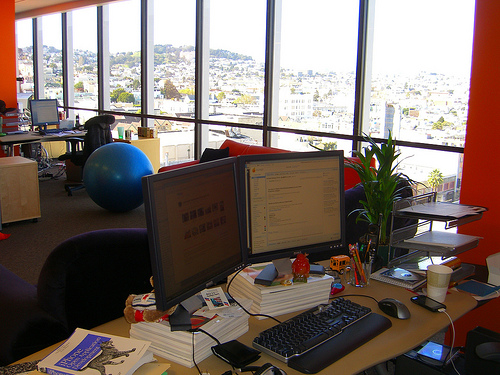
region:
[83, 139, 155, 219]
the ball is blue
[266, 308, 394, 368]
the keyboard is black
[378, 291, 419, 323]
the mouse is grey and black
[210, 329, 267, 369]
wallet is on the table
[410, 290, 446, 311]
iphone is on the table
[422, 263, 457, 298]
the cup is plastic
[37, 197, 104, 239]
the floor is carpeted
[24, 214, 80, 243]
the carpet is brown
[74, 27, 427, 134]
city is in the background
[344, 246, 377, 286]
pens are in the glass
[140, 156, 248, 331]
Black computer monitor on desk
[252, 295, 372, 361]
Black and silver keyboard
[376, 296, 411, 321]
Black and silver mouse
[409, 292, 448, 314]
Black cell phone with charger connected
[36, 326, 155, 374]
White and blue book with picture of cat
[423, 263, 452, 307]
Coffee cup on desk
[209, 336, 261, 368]
Black leather wallet on desk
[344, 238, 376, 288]
Glass cup with pencils in it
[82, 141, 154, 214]
Large blue ball on carpet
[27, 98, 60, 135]
Black computer monitor on desk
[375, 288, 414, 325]
this is a mouse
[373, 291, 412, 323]
a computer mouse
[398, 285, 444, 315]
this is a cell phone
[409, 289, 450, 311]
this is an iPhone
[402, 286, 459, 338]
the iPhone is plugged in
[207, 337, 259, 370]
this is a wallet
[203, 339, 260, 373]
the wallet is black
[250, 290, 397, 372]
this is a keyboard and arm rest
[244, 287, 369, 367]
the keyboard has black keys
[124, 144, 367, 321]
two computer monitors on a stack of books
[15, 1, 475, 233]
Windows in the room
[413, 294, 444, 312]
A cell phone on the desk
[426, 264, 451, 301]
A cup next to the cell phone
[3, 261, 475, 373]
A desk beneath the computer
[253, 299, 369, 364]
A keyboard on the desk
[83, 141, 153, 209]
A giant blue ball by the window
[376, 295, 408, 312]
A computer mouse on the desk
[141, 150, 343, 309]
Computer monitors on top of books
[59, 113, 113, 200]
A chair near the desk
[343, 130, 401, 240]
A plant by the computer monitor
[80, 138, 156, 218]
Dark blue yoga ball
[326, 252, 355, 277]
Tiny yellow school bus toy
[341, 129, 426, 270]
Green potted plant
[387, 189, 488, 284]
Three tier desktop tray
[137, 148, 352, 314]
Two desktop computer screens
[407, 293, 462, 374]
Charging cell phone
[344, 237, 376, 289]
Pencil holder with pencils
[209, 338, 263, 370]
Men's black fold over wallet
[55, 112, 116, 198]
Black desk chair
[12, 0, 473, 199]
View of city through office windows